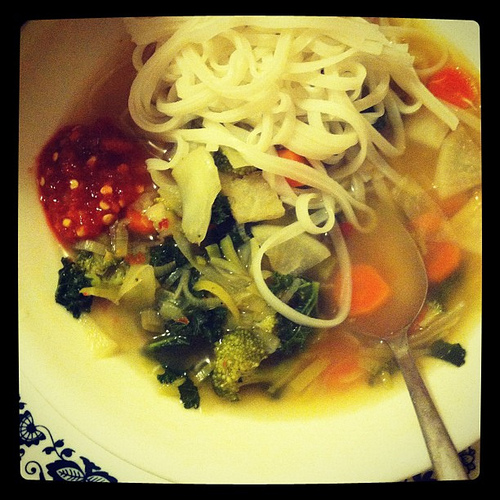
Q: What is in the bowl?
A: Soup.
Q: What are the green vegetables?
A: Broccoli.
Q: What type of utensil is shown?
A: Spoon.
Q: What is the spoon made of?
A: Metal.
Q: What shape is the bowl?
A: Round.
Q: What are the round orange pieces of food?
A: Carrots.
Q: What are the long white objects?
A: Noodles.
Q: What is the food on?
A: Bowl.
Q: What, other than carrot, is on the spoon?
A: Broth.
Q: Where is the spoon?
A: In the soup.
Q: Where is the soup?
A: In the bowl.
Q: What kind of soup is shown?
A: Vegetable soup.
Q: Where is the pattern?
A: On the edge of the bowl.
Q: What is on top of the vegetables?
A: Noodles.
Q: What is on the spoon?
A: A carrot.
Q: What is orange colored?
A: The carrots.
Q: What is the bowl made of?
A: Porcelain.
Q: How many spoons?
A: 1.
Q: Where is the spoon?
A: In the bowel.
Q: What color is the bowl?
A: White.